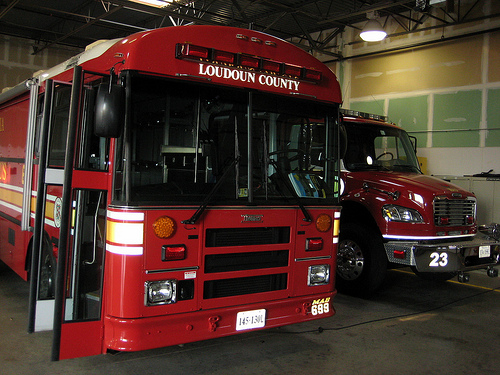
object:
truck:
[1, 22, 343, 363]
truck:
[337, 105, 499, 293]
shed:
[0, 0, 498, 374]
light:
[152, 216, 176, 239]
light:
[315, 213, 333, 233]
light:
[160, 243, 188, 262]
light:
[304, 237, 326, 253]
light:
[145, 279, 178, 307]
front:
[102, 25, 343, 352]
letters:
[199, 60, 301, 94]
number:
[427, 252, 448, 267]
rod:
[0, 0, 500, 56]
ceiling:
[0, 1, 499, 50]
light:
[357, 30, 389, 43]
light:
[128, 0, 180, 10]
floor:
[0, 252, 499, 374]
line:
[393, 266, 499, 295]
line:
[257, 283, 499, 337]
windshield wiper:
[182, 153, 240, 226]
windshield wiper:
[264, 157, 313, 221]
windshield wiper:
[346, 161, 387, 172]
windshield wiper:
[392, 162, 422, 173]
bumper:
[383, 229, 500, 275]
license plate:
[477, 242, 490, 260]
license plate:
[235, 307, 266, 332]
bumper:
[106, 290, 336, 352]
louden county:
[195, 59, 302, 91]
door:
[50, 63, 115, 362]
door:
[25, 76, 118, 323]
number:
[310, 300, 331, 316]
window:
[32, 82, 73, 165]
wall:
[282, 1, 498, 264]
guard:
[21, 76, 35, 232]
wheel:
[336, 205, 379, 303]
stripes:
[0, 181, 146, 257]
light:
[340, 109, 369, 121]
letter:
[197, 59, 207, 76]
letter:
[205, 63, 216, 77]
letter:
[214, 64, 224, 77]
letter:
[223, 66, 233, 79]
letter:
[287, 78, 297, 91]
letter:
[199, 62, 301, 92]